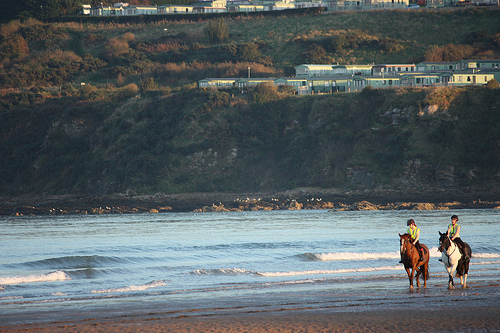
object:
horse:
[398, 233, 430, 293]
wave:
[7, 253, 197, 269]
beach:
[0, 299, 498, 332]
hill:
[1, 89, 498, 210]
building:
[351, 75, 401, 90]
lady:
[398, 219, 423, 264]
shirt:
[407, 226, 419, 238]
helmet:
[407, 219, 415, 226]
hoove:
[409, 285, 414, 289]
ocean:
[0, 207, 499, 315]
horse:
[437, 229, 472, 290]